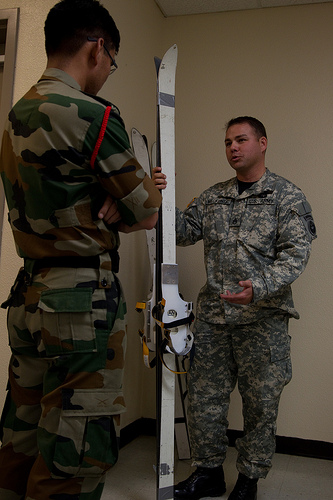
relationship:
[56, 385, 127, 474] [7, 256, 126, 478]
pocket on side of pants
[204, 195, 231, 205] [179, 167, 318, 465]
name tape on uniform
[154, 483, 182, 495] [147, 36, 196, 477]
stripe on bottom of ski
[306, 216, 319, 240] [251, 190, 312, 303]
emblem on sleeve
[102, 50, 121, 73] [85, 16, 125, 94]
glasses on face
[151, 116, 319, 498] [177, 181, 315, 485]
man in uniform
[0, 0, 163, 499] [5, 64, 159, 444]
man in uniform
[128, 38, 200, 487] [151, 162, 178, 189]
skis in hand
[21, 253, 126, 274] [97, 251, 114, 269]
belt in loop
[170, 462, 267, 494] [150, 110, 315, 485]
boots on soldier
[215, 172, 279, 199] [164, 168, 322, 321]
collar of shirt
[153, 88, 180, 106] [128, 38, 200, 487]
tape around skis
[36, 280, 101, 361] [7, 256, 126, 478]
pocket of pants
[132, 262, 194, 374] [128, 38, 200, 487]
boot straps on skis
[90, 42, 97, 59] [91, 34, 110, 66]
eyeglass arm over ear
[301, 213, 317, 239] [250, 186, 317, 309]
emblem on sleeve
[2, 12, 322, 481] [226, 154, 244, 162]
two men standing up talking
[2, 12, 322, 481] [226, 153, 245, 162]
two men standing up talking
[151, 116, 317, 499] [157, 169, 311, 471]
man wearing uniform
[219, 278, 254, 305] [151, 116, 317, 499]
hand of man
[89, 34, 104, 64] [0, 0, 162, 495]
ear of man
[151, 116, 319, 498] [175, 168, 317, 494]
man with military uniforms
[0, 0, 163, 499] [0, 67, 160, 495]
man with military uniforms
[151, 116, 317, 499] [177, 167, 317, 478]
man wearing suit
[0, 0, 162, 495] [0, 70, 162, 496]
man wearing suit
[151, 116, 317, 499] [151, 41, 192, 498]
man holding skis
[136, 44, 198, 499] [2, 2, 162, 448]
skis leaning on wall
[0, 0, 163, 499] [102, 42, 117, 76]
man wearing glasses